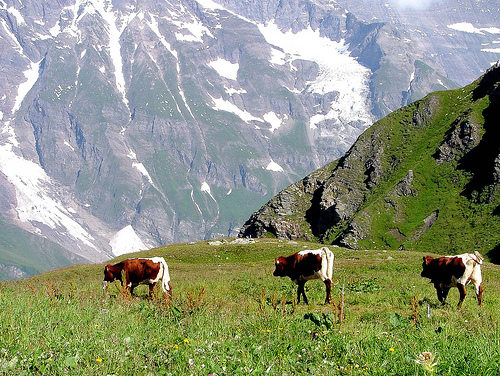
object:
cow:
[103, 256, 171, 294]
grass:
[156, 320, 336, 366]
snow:
[317, 76, 359, 105]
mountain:
[9, 1, 346, 167]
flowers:
[318, 342, 330, 354]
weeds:
[179, 338, 320, 365]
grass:
[38, 309, 191, 367]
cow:
[272, 246, 333, 302]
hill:
[238, 59, 498, 265]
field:
[30, 312, 302, 372]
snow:
[269, 18, 337, 67]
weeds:
[243, 303, 378, 349]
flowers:
[386, 345, 395, 353]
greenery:
[389, 137, 488, 237]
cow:
[420, 250, 482, 306]